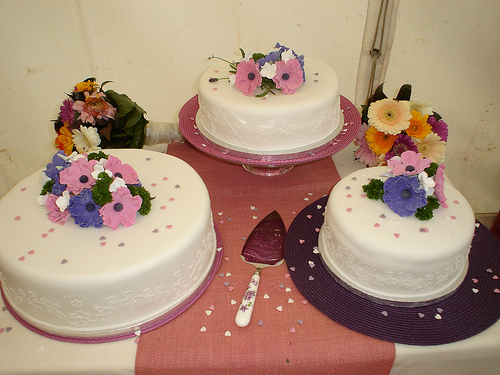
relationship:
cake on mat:
[323, 153, 474, 303] [280, 176, 498, 339]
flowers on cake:
[358, 149, 445, 218] [323, 153, 474, 303]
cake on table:
[195, 57, 345, 156] [3, 136, 498, 372]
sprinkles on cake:
[348, 176, 459, 239] [323, 153, 474, 303]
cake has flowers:
[323, 153, 474, 303] [358, 149, 445, 218]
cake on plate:
[193, 57, 343, 149] [178, 80, 362, 164]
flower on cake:
[386, 177, 424, 212] [323, 153, 474, 303]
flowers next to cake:
[359, 89, 449, 164] [323, 153, 474, 303]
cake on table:
[323, 153, 474, 303] [3, 136, 498, 372]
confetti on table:
[199, 198, 314, 336] [3, 136, 498, 372]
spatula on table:
[227, 210, 290, 328] [3, 136, 498, 372]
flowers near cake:
[359, 89, 449, 164] [323, 153, 474, 303]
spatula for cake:
[227, 210, 290, 328] [323, 153, 474, 303]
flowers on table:
[358, 149, 445, 218] [3, 136, 498, 372]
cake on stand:
[193, 57, 343, 149] [238, 157, 300, 174]